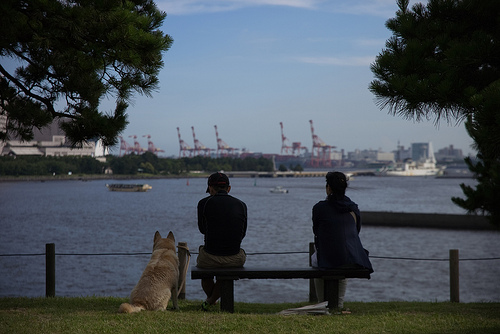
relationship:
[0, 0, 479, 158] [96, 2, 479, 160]
sky has clouds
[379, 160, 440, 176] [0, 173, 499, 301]
boat in water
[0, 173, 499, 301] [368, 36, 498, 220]
water under trees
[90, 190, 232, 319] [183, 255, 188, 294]
dog has leash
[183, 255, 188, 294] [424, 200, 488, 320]
leash tied to pole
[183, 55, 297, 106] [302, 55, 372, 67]
sky has clouds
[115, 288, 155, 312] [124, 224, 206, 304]
tail of dog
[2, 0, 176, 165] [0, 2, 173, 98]
tree has leaves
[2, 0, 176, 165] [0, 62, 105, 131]
tree has branch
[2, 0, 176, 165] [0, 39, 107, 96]
tree has branch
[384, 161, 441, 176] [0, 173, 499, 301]
boat in water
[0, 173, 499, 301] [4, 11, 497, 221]
water under trees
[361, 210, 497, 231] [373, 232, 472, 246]
boat in water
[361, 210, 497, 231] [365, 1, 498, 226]
boat under tree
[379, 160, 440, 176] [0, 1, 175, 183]
boat under trees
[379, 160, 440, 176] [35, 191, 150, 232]
boat in water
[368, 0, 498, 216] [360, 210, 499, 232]
trees on land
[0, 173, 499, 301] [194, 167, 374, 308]
water in front of couple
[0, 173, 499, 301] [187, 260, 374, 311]
water in front of bench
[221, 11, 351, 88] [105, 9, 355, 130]
clouds in sky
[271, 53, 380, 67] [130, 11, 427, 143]
clouds in sky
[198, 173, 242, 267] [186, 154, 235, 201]
man wearing a cap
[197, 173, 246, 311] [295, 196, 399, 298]
man wearing a jacket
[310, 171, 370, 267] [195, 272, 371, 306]
people sitting on bench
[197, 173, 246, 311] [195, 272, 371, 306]
man sitting on bench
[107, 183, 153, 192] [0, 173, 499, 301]
boat in water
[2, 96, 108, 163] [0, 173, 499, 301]
boat in water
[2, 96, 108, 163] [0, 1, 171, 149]
boat under tree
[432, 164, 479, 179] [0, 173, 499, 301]
boat in water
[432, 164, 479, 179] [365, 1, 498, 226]
boat under tree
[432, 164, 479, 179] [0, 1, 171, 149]
boat under tree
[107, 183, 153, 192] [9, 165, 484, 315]
boat in water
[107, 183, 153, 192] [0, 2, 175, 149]
boat under trees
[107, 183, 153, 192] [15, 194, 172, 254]
boat on water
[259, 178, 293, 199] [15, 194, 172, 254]
boat on water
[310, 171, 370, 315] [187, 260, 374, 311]
people sitting on bench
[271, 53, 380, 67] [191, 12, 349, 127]
clouds are in sky